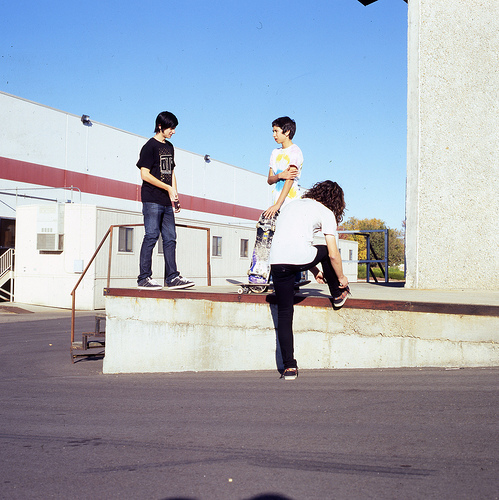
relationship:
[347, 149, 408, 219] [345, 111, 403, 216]
clouds in sky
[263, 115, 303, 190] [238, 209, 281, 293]
boy holding skateboard